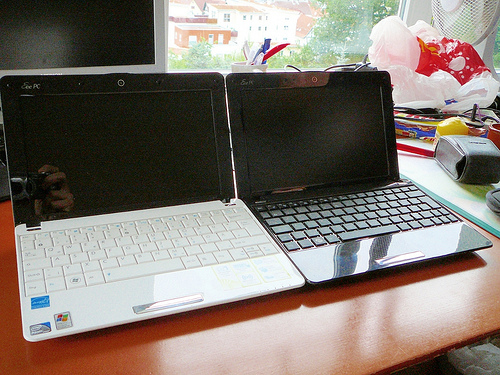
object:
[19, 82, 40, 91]
logo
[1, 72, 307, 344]
laptop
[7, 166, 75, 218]
reflection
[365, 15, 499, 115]
bag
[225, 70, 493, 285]
black laptop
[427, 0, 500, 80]
white fan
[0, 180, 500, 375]
desk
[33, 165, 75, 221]
hand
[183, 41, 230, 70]
plants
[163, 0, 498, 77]
window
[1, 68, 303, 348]
computer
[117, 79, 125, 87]
webcam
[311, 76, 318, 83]
webcam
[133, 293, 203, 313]
touchpad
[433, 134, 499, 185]
case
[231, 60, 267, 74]
cup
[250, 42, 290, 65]
pens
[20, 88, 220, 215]
screen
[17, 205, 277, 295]
keyboard